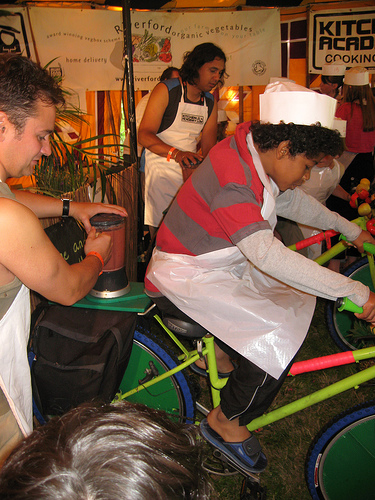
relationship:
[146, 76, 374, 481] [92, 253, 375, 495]
girl on bike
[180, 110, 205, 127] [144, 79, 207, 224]
logo on apron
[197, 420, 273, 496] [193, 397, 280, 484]
sandal on foot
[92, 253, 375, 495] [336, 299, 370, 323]
bike has handlebar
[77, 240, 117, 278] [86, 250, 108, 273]
wrist has bracelet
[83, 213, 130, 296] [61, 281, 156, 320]
blender on top of table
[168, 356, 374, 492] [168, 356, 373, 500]
grass on grass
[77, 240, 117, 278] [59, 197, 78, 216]
wrist has watch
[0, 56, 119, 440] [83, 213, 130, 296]
man using blender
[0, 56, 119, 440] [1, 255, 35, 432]
man has apron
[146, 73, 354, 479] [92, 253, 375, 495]
girl on bike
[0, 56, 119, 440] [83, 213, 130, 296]
man has blender